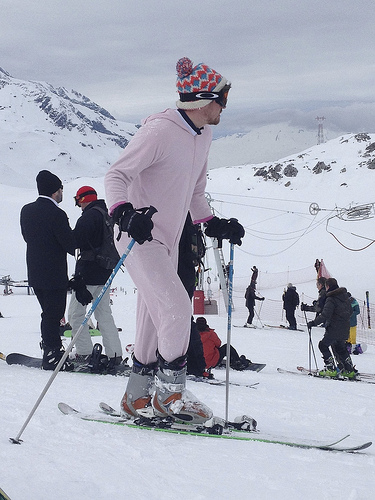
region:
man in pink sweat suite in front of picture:
[96, 52, 240, 436]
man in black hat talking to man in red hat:
[17, 163, 128, 390]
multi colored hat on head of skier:
[170, 53, 233, 121]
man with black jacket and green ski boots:
[304, 274, 367, 390]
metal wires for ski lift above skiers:
[192, 181, 374, 226]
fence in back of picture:
[212, 257, 373, 348]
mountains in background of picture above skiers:
[0, 62, 373, 187]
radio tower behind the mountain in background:
[312, 110, 329, 147]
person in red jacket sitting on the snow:
[194, 315, 258, 377]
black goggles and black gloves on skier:
[98, 54, 249, 433]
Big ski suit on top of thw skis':
[184, 196, 205, 208]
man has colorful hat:
[168, 49, 228, 115]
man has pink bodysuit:
[104, 139, 204, 344]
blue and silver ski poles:
[3, 238, 158, 450]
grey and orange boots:
[109, 346, 252, 445]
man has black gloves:
[113, 198, 169, 268]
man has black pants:
[42, 286, 68, 344]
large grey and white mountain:
[0, 63, 136, 161]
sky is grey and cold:
[30, 8, 137, 84]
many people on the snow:
[0, 55, 373, 461]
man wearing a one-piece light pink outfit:
[105, 107, 214, 363]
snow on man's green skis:
[57, 401, 371, 452]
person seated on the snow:
[195, 315, 266, 375]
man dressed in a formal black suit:
[18, 170, 74, 348]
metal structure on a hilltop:
[208, 113, 372, 218]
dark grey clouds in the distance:
[1, 1, 373, 133]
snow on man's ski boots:
[121, 365, 213, 425]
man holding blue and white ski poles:
[9, 203, 236, 444]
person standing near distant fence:
[233, 261, 313, 290]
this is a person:
[66, 171, 143, 382]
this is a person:
[112, 13, 239, 466]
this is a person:
[190, 289, 267, 391]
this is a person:
[234, 258, 265, 322]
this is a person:
[276, 281, 311, 329]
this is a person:
[315, 279, 361, 381]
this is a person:
[304, 240, 361, 378]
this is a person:
[233, 256, 279, 328]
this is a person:
[176, 277, 276, 397]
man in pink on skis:
[101, 55, 247, 427]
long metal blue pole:
[6, 205, 158, 446]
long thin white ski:
[57, 398, 371, 451]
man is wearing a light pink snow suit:
[104, 57, 247, 426]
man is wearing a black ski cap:
[20, 170, 80, 369]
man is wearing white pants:
[69, 184, 118, 367]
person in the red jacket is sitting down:
[194, 314, 251, 369]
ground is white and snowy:
[0, 133, 373, 499]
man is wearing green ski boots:
[317, 278, 359, 380]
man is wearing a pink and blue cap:
[108, 56, 230, 433]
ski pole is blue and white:
[8, 203, 157, 441]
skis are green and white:
[56, 397, 373, 450]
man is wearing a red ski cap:
[65, 186, 126, 365]